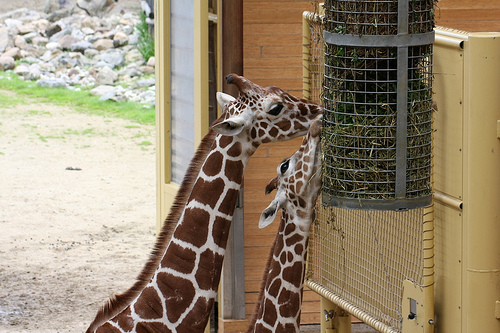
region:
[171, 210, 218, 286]
neck of a giraffe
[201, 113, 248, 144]
right ear of a giraffe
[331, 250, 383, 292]
part of a mesh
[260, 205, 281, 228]
ear of a giraffe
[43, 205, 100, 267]
part of the ground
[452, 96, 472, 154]
edge of a container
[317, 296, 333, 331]
part of a bolt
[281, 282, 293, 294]
white part on the giraffe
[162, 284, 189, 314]
brown part of the giraffe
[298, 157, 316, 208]
jaw of the giraffe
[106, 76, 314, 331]
these are two giraffes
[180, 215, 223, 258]
the fur is brown and white in color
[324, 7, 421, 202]
this is a cage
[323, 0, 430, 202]
the cage is full of grass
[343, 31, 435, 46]
the fence is metallic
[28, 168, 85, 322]
this is the ground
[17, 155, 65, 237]
the ground is sandy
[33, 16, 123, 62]
these are some rocks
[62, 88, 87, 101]
this is some grass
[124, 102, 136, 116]
the grass is green in color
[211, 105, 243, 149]
ear of a giraffe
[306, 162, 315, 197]
jaw of a giraffe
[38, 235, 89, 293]
part of the ground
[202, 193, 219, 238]
part of a white line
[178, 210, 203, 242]
part of a brown patch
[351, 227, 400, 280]
part of a mesh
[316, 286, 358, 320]
part of a metal edge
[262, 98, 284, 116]
right eye of a giraffe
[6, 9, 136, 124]
pile of rocks in the grass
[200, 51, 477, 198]
giraffes eating grass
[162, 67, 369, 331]
two giraffes in the building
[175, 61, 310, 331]
the giraffes are brown and white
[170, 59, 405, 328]
the giraffes have long necks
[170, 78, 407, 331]
one giraffe is smaller than the other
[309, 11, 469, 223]
grass is in a metal round feeder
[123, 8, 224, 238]
the door is open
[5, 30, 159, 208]
light coming in to the building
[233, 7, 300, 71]
building is made with wood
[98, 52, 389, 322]
two giraffes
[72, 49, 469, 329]
two giraffes are eating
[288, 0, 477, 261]
a metal container holding hay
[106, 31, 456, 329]
the giraffes eat from a metal basket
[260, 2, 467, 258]
the metal food basket is attached to a wall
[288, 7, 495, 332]
the building has a yellow metal wall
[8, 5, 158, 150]
a pile of rocks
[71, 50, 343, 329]
the giraffes are very young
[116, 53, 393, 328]
the giraffes are brown and white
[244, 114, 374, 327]
the smallest girafee is reaching it's head up for the food